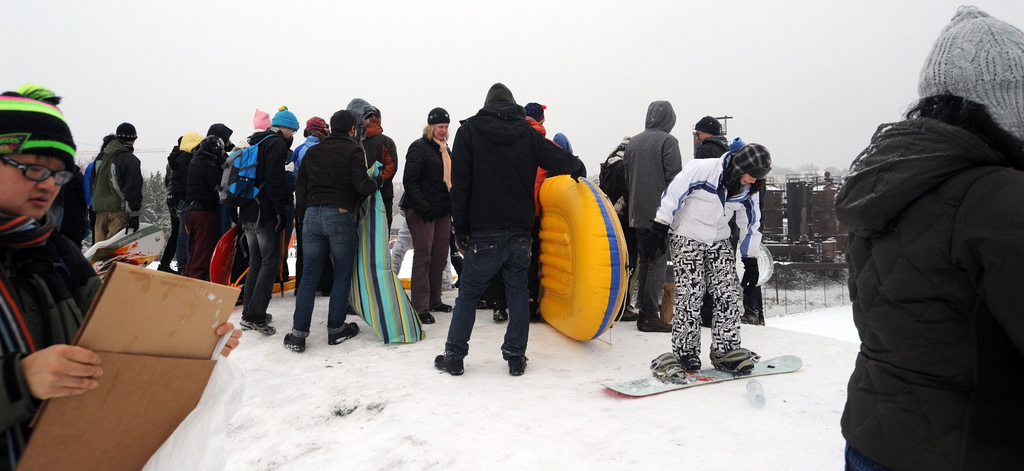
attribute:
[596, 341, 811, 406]
snowboard — white 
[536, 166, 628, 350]
toboggan — yellow 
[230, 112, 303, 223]
child — young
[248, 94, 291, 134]
cap — pink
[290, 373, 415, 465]
footprints — deep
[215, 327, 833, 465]
snow — white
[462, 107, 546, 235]
jacket — black 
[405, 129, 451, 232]
jacket — black 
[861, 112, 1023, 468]
jacket — black 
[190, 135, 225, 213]
jacket — black 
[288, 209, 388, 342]
jeans — blue 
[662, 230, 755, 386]
pants — black, white, zebra, snow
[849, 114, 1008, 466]
jacket — black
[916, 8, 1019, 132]
cap — grey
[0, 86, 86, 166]
black cap — black 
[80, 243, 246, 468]
box — cardboard, tan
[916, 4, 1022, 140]
beanie — knit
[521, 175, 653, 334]
sled — yellow, blue, blow up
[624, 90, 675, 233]
coat — gray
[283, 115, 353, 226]
coat — black 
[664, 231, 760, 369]
pants — black, white, ski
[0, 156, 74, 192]
glasses — black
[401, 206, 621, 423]
pants — black, white, patterned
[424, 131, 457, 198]
scarf — pink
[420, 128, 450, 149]
woman's neck — woman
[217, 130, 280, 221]
strap — black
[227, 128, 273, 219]
trim — black